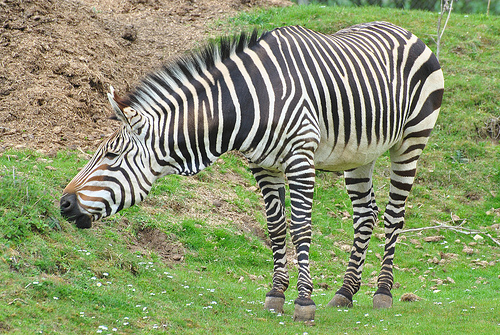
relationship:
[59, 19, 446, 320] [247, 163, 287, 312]
striped zebra has leg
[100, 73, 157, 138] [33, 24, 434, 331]
ears belong to zebra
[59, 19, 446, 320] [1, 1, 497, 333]
striped zebra standing in field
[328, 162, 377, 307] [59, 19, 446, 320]
leg belongs striped zebra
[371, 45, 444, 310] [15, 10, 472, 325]
leg of zebra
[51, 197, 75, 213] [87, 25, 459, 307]
nose to zebra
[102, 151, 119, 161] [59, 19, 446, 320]
eye to striped zebra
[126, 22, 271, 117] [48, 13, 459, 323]
mane on zebra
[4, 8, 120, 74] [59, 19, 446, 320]
hill behind striped zebra